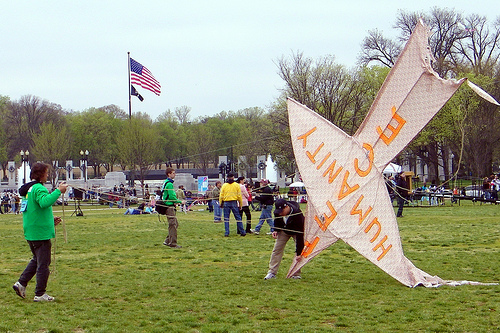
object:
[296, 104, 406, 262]
lettering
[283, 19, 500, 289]
kite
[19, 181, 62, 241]
jacket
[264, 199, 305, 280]
man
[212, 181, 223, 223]
person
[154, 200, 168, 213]
case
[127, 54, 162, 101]
flags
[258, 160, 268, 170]
wreath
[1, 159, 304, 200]
building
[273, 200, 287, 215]
hat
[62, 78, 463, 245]
string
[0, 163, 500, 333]
ground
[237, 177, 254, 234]
person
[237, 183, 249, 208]
sweater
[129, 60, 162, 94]
flag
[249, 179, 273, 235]
person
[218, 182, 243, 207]
jacket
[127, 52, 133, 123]
pole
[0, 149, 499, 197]
background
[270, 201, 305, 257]
jacket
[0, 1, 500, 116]
sky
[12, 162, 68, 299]
people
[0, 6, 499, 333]
park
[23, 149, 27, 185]
light pole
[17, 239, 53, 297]
pants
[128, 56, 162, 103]
blue flag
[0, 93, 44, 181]
trees